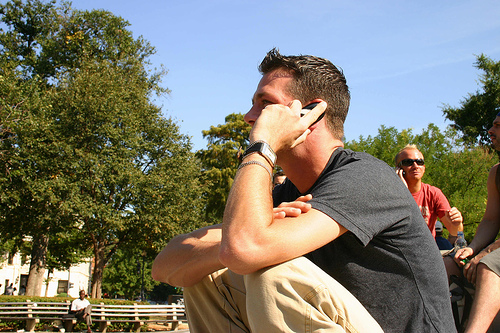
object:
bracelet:
[236, 160, 272, 178]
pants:
[183, 255, 384, 332]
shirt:
[274, 148, 456, 332]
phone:
[301, 100, 325, 128]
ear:
[304, 98, 325, 128]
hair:
[257, 45, 350, 139]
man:
[392, 143, 464, 237]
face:
[399, 149, 427, 178]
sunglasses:
[396, 158, 425, 166]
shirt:
[410, 182, 450, 237]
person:
[71, 289, 94, 332]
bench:
[1, 300, 183, 322]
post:
[172, 302, 178, 321]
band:
[243, 142, 262, 158]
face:
[261, 142, 278, 167]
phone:
[396, 166, 406, 176]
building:
[0, 221, 94, 298]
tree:
[1, 2, 156, 299]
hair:
[395, 144, 417, 162]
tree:
[84, 113, 202, 298]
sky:
[139, 1, 500, 55]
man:
[180, 55, 453, 332]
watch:
[238, 140, 279, 164]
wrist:
[234, 141, 278, 189]